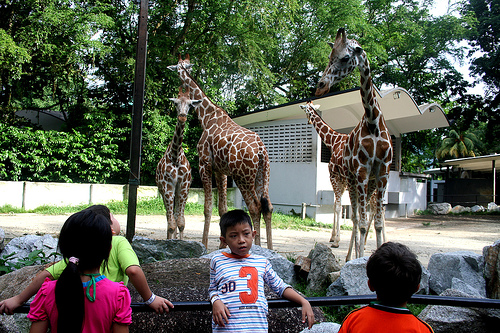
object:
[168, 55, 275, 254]
giraffe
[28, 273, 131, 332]
shirt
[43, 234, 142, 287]
shirt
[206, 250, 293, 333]
shirt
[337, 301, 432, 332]
shirt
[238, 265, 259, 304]
number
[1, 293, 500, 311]
bar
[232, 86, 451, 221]
building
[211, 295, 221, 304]
wristband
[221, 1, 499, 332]
right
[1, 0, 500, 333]
zoo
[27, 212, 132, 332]
girl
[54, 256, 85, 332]
pony tail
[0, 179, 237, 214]
fence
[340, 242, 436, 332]
boy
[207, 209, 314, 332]
boy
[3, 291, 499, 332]
fence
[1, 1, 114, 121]
trees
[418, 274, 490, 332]
rocks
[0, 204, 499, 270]
ground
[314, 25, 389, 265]
giraffe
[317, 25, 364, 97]
head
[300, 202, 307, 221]
post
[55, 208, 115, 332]
hair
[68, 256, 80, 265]
tie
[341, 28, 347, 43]
horns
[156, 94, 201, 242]
giraffe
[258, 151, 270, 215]
tail